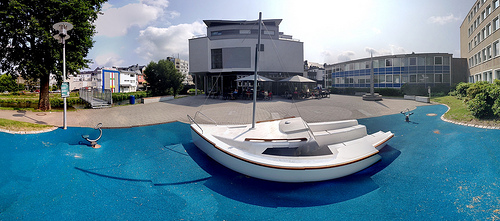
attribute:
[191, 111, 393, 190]
boat — white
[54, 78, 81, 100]
sign — green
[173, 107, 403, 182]
boat — white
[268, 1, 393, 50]
sun — bright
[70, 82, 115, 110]
bridge — small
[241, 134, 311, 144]
railing — red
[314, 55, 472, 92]
building — grey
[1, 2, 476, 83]
sky — sunny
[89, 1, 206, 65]
white clouds — puffy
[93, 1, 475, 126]
building — white, red, blue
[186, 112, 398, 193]
sailboat — white, brown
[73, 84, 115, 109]
walkway — metal